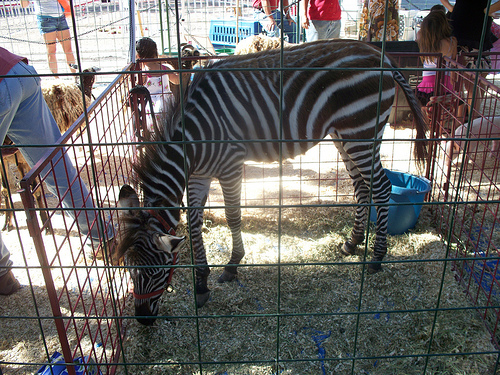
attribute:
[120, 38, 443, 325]
zebra — eating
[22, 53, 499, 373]
cage — metal, huge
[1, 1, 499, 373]
wiring — green, metal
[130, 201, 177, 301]
halter — red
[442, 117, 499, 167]
pig — pink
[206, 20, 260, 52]
pet carrier — green, plastic, blue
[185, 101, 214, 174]
stripe — black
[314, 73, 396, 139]
stripe — black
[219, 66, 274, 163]
stripe — black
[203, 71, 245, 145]
stripe — white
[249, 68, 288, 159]
stripe — white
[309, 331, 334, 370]
tarp — blue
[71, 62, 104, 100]
goat — black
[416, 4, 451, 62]
hair — long, brown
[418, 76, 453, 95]
skirt — pink, bright pink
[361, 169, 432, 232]
bucket — blue, big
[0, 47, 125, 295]
person — leaning over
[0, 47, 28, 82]
shirt — red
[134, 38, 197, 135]
girl — little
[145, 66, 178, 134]
dress — white, flowered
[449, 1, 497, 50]
top — black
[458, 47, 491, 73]
shorts — white, black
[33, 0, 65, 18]
shirt — white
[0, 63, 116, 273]
jeans — blue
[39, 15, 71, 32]
shorts — blue jean shorts, blue